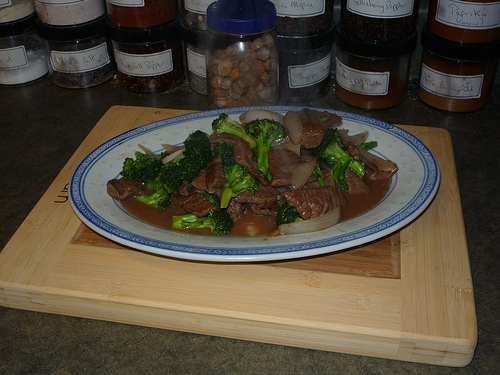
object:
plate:
[67, 103, 442, 265]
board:
[0, 104, 479, 369]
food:
[109, 110, 398, 237]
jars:
[416, 28, 499, 116]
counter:
[1, 84, 500, 370]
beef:
[280, 182, 341, 222]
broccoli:
[132, 158, 178, 211]